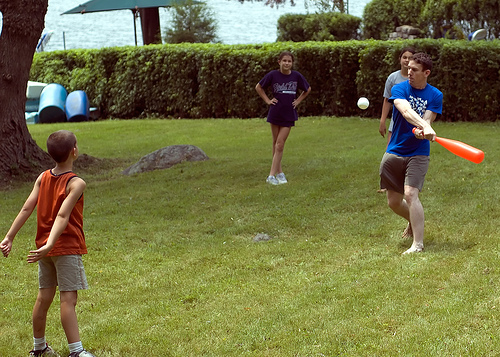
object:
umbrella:
[57, 0, 212, 50]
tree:
[0, 0, 98, 180]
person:
[0, 128, 94, 356]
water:
[36, 0, 374, 57]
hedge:
[28, 35, 499, 122]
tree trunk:
[0, 0, 95, 185]